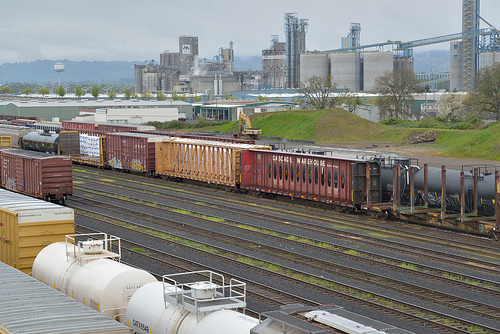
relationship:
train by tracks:
[9, 124, 499, 220] [101, 183, 250, 219]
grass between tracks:
[255, 110, 325, 139] [101, 183, 250, 219]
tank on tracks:
[33, 231, 165, 313] [101, 183, 250, 219]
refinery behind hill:
[270, 3, 491, 103] [247, 106, 361, 151]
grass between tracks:
[169, 205, 231, 230] [101, 183, 250, 219]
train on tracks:
[9, 124, 499, 220] [101, 183, 250, 219]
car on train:
[152, 140, 241, 184] [9, 124, 499, 220]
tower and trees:
[49, 59, 71, 98] [21, 84, 187, 105]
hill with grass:
[247, 106, 361, 151] [255, 110, 325, 139]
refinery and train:
[270, 3, 491, 103] [9, 124, 499, 220]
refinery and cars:
[270, 3, 491, 103] [104, 117, 376, 212]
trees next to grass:
[21, 84, 187, 105] [255, 110, 325, 139]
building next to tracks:
[175, 33, 203, 90] [101, 183, 250, 219]